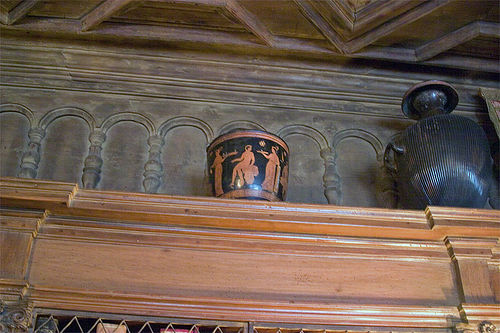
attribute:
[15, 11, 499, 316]
scene — outdoors